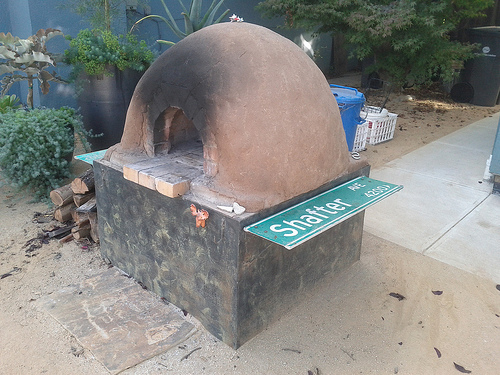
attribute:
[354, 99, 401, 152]
crates — white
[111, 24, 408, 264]
pizza oven — clay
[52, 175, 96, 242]
fire wood — stacked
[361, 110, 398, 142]
plastic bin — white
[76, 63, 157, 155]
container — plastic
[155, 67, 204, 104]
residue — black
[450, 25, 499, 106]
garbage can — plastic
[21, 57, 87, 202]
plant — potted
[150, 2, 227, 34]
plant — aloe vera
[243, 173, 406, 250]
sign — green